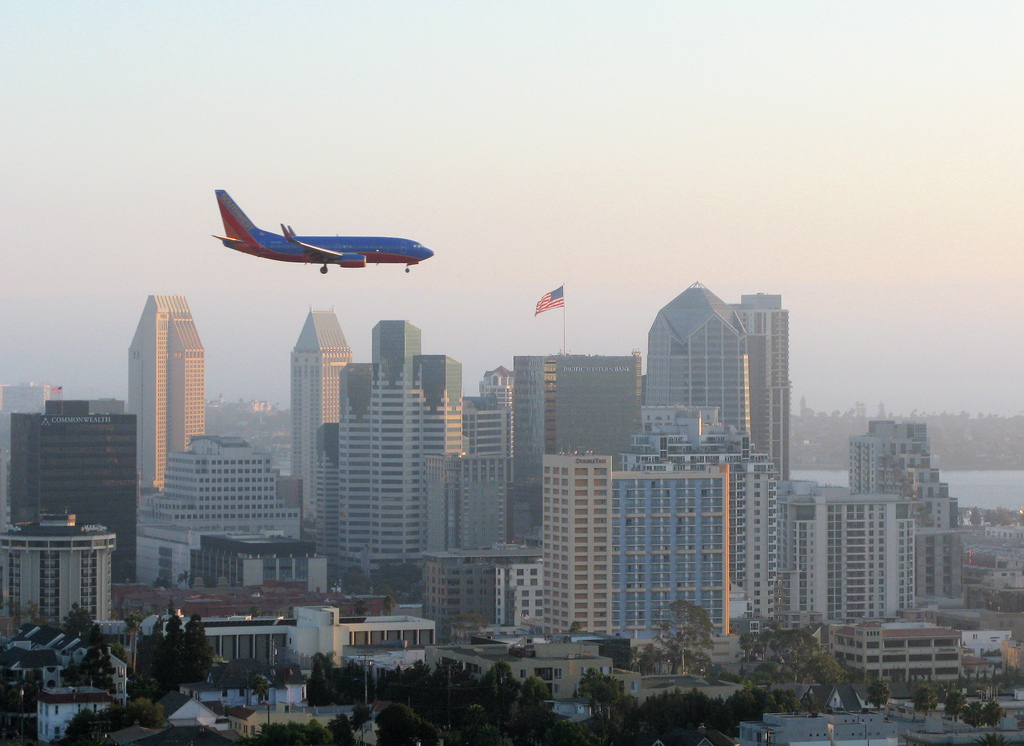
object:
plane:
[214, 189, 435, 275]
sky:
[0, 2, 1024, 407]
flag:
[534, 283, 566, 355]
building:
[515, 352, 646, 552]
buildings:
[0, 282, 1022, 746]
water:
[789, 468, 1024, 516]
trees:
[2, 603, 1023, 746]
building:
[641, 279, 750, 453]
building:
[339, 319, 463, 565]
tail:
[214, 189, 264, 252]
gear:
[320, 262, 419, 275]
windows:
[375, 371, 407, 558]